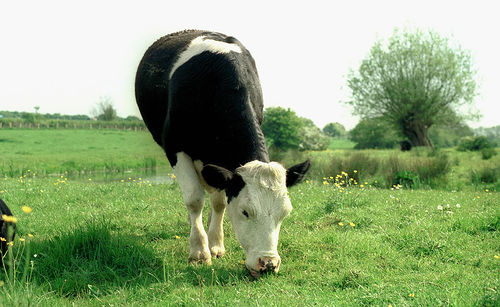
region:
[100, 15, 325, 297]
Cow is eating grass.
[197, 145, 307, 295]
Cow's head is white.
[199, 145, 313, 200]
Cow's ears are black.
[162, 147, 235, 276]
Cow's legs are white.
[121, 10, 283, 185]
Cow's body is predominantly black.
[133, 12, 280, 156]
White patch of hair on cow's back.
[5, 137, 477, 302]
Grass is green.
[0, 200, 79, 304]
Yellow flowers grow amid the grass.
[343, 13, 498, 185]
Tree in background is green.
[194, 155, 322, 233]
Cow's eyes are open.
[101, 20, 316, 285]
This is a cow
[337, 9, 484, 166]
This is a tree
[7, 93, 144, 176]
This is a field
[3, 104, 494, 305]
This is a pasture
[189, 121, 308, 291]
This is a cow's head.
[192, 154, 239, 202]
This is a cow's right ear.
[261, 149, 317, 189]
This is a cows left ear.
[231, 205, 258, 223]
This is a cow's eye.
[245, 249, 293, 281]
This is a cow's nose.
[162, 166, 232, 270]
These are cows legs.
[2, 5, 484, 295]
Cow grazing in a pasture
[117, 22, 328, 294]
The cow is blavk and white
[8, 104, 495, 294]
The pasture is green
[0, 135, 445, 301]
Wild dandelions are growing in the pasture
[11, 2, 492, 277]
A mature tree is in the background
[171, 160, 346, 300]
The cow's eyes are black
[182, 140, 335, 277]
The cows ears are black and it's head is white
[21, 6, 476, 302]
It's daytime and the sky is partly cloudy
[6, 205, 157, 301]
Tall dark green grassy patch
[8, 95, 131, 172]
Fence in the background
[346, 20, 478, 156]
a green leafy tree behind the cow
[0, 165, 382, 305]
Patches of yellow flowers grow on the ground around the cow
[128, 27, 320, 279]
the cow is black and white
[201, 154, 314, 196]
the cow has black ears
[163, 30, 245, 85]
the cow has a white spot on his back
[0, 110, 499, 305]
the ground is lush, grassy, and green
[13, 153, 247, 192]
there is a small pond behind the cow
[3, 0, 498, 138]
the sky is bright and sunny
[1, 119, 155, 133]
a long fence is behind the cow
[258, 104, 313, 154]
a green leafy bush is behind the cow on the other side of the pond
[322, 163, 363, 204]
the flowers are yellow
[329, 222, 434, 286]
the grass is green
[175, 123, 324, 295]
the cow is eating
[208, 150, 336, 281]
the cow's head is white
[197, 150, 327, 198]
the cow's ears are black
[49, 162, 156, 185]
water beside the flowers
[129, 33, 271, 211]
the cow's body is black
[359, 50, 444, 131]
the tree's leaves are green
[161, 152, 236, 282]
cow's feet are white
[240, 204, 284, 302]
the cow is eating grass